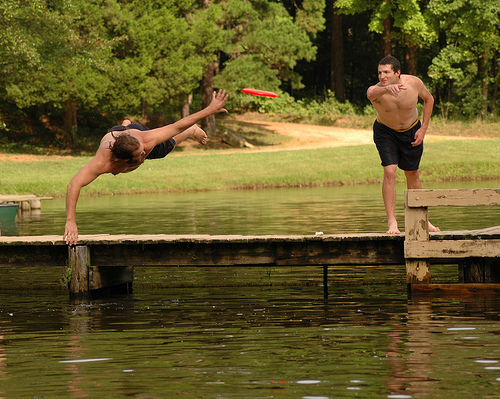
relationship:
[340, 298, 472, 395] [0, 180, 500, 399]
reflection on lake water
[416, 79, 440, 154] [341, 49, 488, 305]
hand of man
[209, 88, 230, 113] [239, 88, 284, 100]
hand catching frisbee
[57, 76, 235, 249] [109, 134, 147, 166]
man has head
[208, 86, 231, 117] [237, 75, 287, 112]
hand reaching for frisbee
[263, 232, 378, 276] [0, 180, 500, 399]
dock over lake water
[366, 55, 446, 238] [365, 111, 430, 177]
man wearing black shorts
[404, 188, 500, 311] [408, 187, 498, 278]
fence covered with paint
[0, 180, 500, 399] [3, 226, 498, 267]
lake water below dock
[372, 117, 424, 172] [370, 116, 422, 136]
black shorts with waistband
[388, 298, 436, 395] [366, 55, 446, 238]
reflection of man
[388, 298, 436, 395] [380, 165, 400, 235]
reflection of leg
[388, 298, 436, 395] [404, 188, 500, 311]
reflection of fence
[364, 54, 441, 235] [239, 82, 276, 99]
man throwing a frisbee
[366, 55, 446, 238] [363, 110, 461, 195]
man wearing shorts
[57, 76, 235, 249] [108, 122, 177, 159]
man in black shorts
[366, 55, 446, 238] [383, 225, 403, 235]
man has foot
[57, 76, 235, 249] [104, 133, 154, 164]
man has head